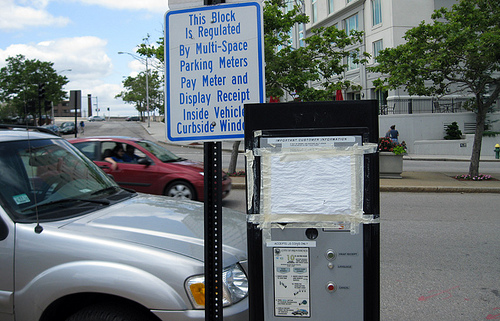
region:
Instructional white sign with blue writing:
[144, 3, 271, 142]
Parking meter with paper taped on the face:
[228, 92, 407, 316]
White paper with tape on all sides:
[243, 135, 380, 231]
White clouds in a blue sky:
[56, 24, 112, 74]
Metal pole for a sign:
[201, 137, 228, 318]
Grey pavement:
[404, 220, 468, 262]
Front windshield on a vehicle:
[5, 130, 129, 230]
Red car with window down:
[62, 127, 232, 211]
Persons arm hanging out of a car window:
[95, 134, 155, 172]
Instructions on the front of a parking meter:
[266, 232, 321, 318]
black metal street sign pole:
[193, 144, 230, 318]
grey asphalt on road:
[390, 192, 481, 318]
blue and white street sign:
[157, 8, 264, 138]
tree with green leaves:
[2, 60, 67, 121]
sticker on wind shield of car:
[11, 186, 36, 209]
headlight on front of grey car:
[171, 247, 248, 309]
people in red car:
[105, 139, 143, 166]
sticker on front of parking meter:
[261, 244, 318, 319]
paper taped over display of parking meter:
[255, 143, 368, 224]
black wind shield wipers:
[30, 165, 137, 221]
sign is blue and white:
[143, 18, 273, 172]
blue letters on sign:
[182, 15, 242, 150]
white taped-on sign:
[240, 124, 355, 246]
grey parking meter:
[240, 218, 346, 318]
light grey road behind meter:
[363, 183, 471, 309]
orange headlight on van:
[165, 255, 242, 315]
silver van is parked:
[13, 148, 181, 312]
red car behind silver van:
[35, 119, 235, 186]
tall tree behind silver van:
[6, 51, 77, 138]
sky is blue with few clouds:
[54, 16, 131, 105]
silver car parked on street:
[0, 126, 252, 315]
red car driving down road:
[65, 128, 220, 198]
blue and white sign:
[168, 1, 265, 143]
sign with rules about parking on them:
[172, 2, 257, 137]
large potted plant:
[375, 136, 411, 179]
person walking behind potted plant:
[385, 121, 407, 136]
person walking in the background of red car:
[78, 118, 89, 137]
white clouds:
[3, 1, 162, 103]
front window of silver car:
[1, 141, 136, 222]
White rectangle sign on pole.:
[158, 15, 273, 168]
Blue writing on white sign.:
[164, 42, 261, 167]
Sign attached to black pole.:
[188, 134, 237, 316]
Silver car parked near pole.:
[64, 190, 161, 316]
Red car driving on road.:
[122, 139, 213, 219]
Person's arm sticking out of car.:
[100, 151, 129, 183]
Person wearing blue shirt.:
[113, 151, 133, 170]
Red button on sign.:
[319, 275, 349, 308]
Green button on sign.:
[319, 245, 352, 268]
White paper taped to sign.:
[246, 135, 403, 250]